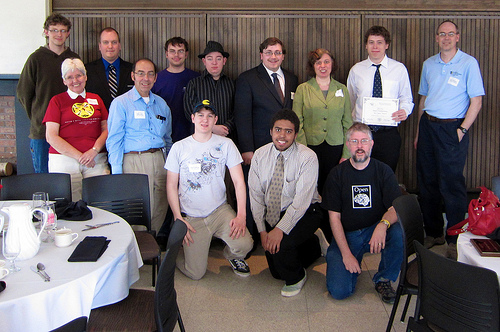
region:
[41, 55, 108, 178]
a woman in a red shirt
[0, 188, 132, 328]
a large round table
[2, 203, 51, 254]
a tall white pitcher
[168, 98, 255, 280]
a boy in a black cap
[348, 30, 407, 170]
a boy holding up a certificate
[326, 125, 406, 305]
a man in a black shirt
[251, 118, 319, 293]
a man in a shirt and tie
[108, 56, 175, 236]
a man in a blue button down shirt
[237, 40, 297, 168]
a man in a suit and tie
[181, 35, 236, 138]
a boy wearing a fedora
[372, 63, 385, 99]
a blue neck tie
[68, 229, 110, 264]
black cloth napkin on the table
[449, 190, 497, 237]
a red purse on the table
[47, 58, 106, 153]
a woman with a white collar on her shirt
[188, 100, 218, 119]
baseball hat with a C on it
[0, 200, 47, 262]
white coffee container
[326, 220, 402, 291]
man is wearing blue jeans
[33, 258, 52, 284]
silver spoon on the table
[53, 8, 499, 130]
wood paneling on the wall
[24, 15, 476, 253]
the people are posing for a picture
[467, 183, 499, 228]
red purse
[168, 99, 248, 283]
young man wearing a baseball cap and brown pants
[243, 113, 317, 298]
young man wearing a tie and a brown shirt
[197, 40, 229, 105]
young man wearing a striped shirt and black hat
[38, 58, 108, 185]
woman wearing a red and yellow shirt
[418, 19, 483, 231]
man wearing a light blue shirt and dark blue pants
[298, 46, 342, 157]
woman wearing a green jacket with three buttons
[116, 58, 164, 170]
man with glasses wearing brown pants and a blue shirt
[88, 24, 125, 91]
man wearing a blue shirt and a black suit jacket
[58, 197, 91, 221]
black cloth napkin on a table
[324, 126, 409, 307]
Man wearing a black shirt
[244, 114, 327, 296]
Man wearing black pants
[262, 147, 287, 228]
Tie around the man's neck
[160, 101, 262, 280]
Man kneeling on the floor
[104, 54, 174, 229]
Man wearing a blue shirt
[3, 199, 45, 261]
Picture on the table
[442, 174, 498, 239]
Purse on the table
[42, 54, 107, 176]
Woman wearing a red shirt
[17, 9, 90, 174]
Man wearing a brown sweater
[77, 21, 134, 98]
Man wearing a black jacket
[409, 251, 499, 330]
part of a black chair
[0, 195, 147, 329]
part of a white tablecloth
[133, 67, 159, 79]
a man's eyeglasses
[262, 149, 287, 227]
a man's long brown tie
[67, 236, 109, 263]
a black table napkin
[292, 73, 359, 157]
a woman's green blazer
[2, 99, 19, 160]
part of a brick wall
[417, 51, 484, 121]
a man's blue shirt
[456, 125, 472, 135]
a man's black watch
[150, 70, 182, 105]
part of a man's blue shirt